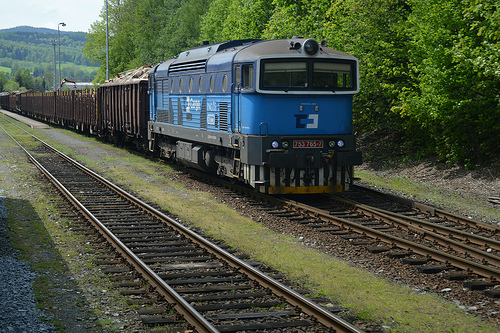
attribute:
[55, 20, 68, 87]
lamp post — lighted, tall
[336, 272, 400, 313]
grass — green, yellow, short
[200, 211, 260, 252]
grass — green, yellow, short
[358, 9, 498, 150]
bushes — green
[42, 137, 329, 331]
track — brown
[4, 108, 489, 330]
grass — green, yellow, short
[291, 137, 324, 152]
numbers — white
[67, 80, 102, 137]
train compartment — cargo, brown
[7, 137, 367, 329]
tracks — metal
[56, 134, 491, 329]
grass — short, yellow, green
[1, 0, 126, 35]
sky — white